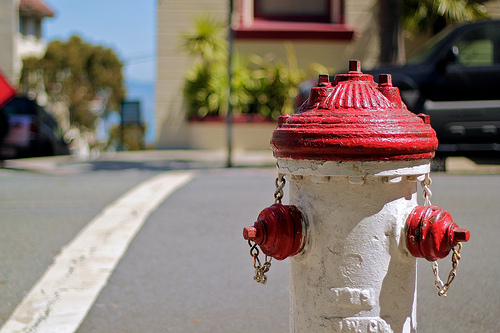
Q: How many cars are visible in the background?
A: Two.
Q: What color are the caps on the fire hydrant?
A: Red.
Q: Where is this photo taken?
A: Street.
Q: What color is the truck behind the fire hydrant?
A: Black.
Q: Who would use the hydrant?
A: Fire Fighters.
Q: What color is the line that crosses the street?
A: White.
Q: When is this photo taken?
A: Daytime.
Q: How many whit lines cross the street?
A: One.